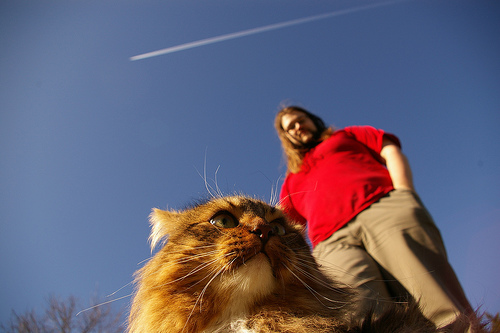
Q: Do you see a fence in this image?
A: No, there are no fences.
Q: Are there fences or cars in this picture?
A: No, there are no fences or cars.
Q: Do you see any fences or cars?
A: No, there are no fences or cars.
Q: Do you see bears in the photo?
A: No, there are no bears.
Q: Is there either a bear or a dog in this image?
A: No, there are no bears or dogs.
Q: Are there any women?
A: No, there are no women.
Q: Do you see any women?
A: No, there are no women.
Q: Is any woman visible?
A: No, there are no women.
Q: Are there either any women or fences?
A: No, there are no women or fences.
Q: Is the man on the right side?
A: Yes, the man is on the right of the image.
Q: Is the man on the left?
A: No, the man is on the right of the image.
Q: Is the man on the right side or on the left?
A: The man is on the right of the image.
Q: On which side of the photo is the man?
A: The man is on the right of the image.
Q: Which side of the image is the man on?
A: The man is on the right of the image.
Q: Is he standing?
A: Yes, the man is standing.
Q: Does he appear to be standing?
A: Yes, the man is standing.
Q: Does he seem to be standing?
A: Yes, the man is standing.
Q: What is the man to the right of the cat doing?
A: The man is standing.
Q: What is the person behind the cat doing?
A: The man is standing.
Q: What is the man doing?
A: The man is standing.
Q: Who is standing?
A: The man is standing.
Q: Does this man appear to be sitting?
A: No, the man is standing.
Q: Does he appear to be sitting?
A: No, the man is standing.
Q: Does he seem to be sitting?
A: No, the man is standing.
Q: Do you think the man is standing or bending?
A: The man is standing.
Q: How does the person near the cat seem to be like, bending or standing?
A: The man is standing.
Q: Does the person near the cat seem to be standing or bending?
A: The man is standing.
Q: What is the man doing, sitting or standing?
A: The man is standing.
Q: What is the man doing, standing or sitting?
A: The man is standing.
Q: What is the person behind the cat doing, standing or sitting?
A: The man is standing.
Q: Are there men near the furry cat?
A: Yes, there is a man near the cat.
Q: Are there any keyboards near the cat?
A: No, there is a man near the cat.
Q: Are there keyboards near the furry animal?
A: No, there is a man near the cat.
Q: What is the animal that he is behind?
A: The animal is a cat.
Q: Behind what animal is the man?
A: The man is behind the cat.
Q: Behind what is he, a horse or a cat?
A: The man is behind a cat.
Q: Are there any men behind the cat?
A: Yes, there is a man behind the cat.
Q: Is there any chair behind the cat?
A: No, there is a man behind the cat.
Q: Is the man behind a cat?
A: Yes, the man is behind a cat.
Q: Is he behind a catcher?
A: No, the man is behind a cat.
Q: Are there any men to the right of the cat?
A: Yes, there is a man to the right of the cat.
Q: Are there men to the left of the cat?
A: No, the man is to the right of the cat.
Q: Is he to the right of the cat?
A: Yes, the man is to the right of the cat.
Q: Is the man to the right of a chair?
A: No, the man is to the right of the cat.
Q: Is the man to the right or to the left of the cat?
A: The man is to the right of the cat.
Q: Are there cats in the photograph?
A: Yes, there is a cat.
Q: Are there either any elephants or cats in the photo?
A: Yes, there is a cat.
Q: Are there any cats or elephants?
A: Yes, there is a cat.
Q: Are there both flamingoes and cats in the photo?
A: No, there is a cat but no flamingoes.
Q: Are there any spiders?
A: No, there are no spiders.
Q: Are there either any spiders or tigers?
A: No, there are no spiders or tigers.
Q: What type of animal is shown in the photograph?
A: The animal is a cat.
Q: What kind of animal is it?
A: The animal is a cat.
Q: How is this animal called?
A: This is a cat.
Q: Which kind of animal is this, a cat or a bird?
A: This is a cat.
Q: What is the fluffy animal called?
A: The animal is a cat.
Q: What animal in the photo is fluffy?
A: The animal is a cat.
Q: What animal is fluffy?
A: The animal is a cat.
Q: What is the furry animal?
A: The animal is a cat.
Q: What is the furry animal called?
A: The animal is a cat.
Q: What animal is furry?
A: The animal is a cat.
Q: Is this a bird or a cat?
A: This is a cat.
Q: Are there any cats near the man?
A: Yes, there is a cat near the man.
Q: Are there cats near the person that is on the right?
A: Yes, there is a cat near the man.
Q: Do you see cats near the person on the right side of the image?
A: Yes, there is a cat near the man.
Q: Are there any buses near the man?
A: No, there is a cat near the man.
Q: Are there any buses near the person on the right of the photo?
A: No, there is a cat near the man.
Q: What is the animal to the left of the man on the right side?
A: The animal is a cat.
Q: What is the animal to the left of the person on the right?
A: The animal is a cat.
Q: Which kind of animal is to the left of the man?
A: The animal is a cat.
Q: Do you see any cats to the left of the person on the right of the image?
A: Yes, there is a cat to the left of the man.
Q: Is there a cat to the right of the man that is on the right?
A: No, the cat is to the left of the man.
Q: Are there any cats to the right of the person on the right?
A: No, the cat is to the left of the man.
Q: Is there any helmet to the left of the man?
A: No, there is a cat to the left of the man.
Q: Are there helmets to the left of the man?
A: No, there is a cat to the left of the man.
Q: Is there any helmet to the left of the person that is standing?
A: No, there is a cat to the left of the man.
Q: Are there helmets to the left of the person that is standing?
A: No, there is a cat to the left of the man.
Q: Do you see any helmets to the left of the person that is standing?
A: No, there is a cat to the left of the man.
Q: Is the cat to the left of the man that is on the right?
A: Yes, the cat is to the left of the man.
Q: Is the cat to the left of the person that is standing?
A: Yes, the cat is to the left of the man.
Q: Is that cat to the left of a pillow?
A: No, the cat is to the left of the man.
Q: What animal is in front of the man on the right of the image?
A: The cat is in front of the man.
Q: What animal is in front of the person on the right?
A: The cat is in front of the man.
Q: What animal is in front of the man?
A: The cat is in front of the man.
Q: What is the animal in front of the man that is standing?
A: The animal is a cat.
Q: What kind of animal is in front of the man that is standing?
A: The animal is a cat.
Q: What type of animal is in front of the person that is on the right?
A: The animal is a cat.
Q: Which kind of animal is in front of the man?
A: The animal is a cat.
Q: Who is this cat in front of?
A: The cat is in front of the man.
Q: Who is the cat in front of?
A: The cat is in front of the man.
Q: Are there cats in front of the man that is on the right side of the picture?
A: Yes, there is a cat in front of the man.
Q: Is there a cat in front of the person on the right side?
A: Yes, there is a cat in front of the man.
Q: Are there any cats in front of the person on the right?
A: Yes, there is a cat in front of the man.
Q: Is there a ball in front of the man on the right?
A: No, there is a cat in front of the man.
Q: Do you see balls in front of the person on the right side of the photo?
A: No, there is a cat in front of the man.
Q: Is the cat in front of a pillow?
A: No, the cat is in front of the man.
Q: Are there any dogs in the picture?
A: No, there are no dogs.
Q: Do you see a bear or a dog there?
A: No, there are no dogs or bears.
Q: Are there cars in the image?
A: No, there are no cars.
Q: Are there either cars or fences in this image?
A: No, there are no cars or fences.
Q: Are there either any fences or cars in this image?
A: No, there are no cars or fences.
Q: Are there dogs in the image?
A: No, there are no dogs.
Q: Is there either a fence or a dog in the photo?
A: No, there are no dogs or fences.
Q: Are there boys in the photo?
A: No, there are no boys.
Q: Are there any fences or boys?
A: No, there are no boys or fences.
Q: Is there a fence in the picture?
A: No, there are no fences.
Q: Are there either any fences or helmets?
A: No, there are no fences or helmets.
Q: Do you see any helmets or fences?
A: No, there are no fences or helmets.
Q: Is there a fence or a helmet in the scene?
A: No, there are no fences or helmets.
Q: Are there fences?
A: No, there are no fences.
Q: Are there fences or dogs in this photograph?
A: No, there are no fences or dogs.